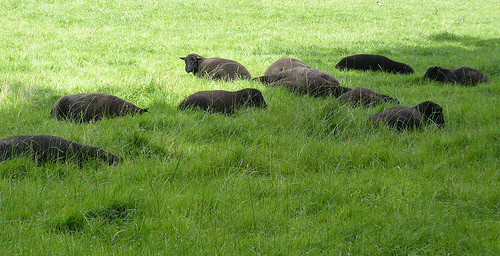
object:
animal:
[0, 131, 118, 167]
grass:
[8, 157, 465, 252]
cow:
[178, 85, 272, 121]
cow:
[48, 85, 153, 125]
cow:
[178, 45, 258, 84]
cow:
[256, 51, 348, 101]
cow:
[335, 81, 400, 108]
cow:
[368, 97, 450, 138]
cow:
[421, 59, 494, 91]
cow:
[0, 130, 125, 179]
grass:
[2, 1, 497, 50]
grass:
[0, 171, 498, 253]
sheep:
[176, 50, 254, 85]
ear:
[177, 54, 189, 61]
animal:
[412, 95, 454, 124]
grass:
[223, 123, 446, 223]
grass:
[183, 115, 388, 254]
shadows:
[375, 22, 499, 67]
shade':
[1, 39, 500, 254]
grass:
[115, 133, 452, 241]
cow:
[336, 53, 415, 83]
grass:
[340, 64, 417, 98]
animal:
[51, 92, 146, 122]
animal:
[369, 100, 428, 136]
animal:
[422, 63, 487, 85]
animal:
[337, 48, 416, 77]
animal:
[173, 85, 270, 117]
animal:
[258, 56, 350, 97]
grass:
[0, 3, 496, 253]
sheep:
[177, 87, 267, 114]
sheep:
[365, 101, 443, 130]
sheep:
[52, 92, 148, 123]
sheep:
[337, 52, 413, 73]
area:
[45, 192, 146, 240]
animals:
[0, 47, 499, 171]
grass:
[255, 81, 365, 158]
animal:
[334, 82, 396, 107]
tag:
[191, 47, 208, 64]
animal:
[166, 43, 253, 83]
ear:
[194, 52, 204, 62]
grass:
[305, 82, 374, 144]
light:
[1, 0, 499, 100]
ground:
[1, 1, 499, 251]